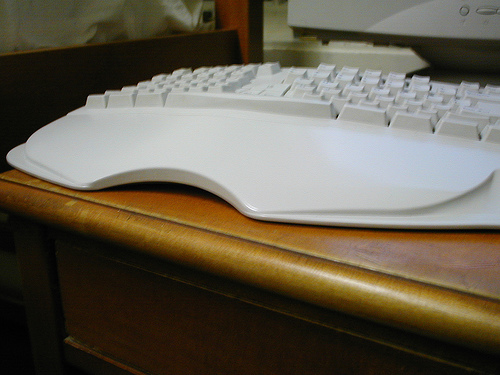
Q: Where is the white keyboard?
A: On the desk.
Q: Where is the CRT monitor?
A: Behind the keyboard.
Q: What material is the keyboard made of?
A: Plastic.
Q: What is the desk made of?
A: Wood.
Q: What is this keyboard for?
A: Personal computers.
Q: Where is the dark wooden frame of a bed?
A: Behind the desk.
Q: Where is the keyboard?
A: On the wood desk.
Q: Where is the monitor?
A: Behind the keyboard.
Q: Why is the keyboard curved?
A: The keyboard is ergonomic.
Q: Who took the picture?
A: A keyboard photographer.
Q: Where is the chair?
A: Beside the desk.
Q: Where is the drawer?
A: In front of the desk.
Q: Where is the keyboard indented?
A: At the bottom.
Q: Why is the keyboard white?
A: To match the monitor.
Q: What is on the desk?
A: A keyboard.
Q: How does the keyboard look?
A: White.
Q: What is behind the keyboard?
A: A monitor.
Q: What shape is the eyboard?
A: Curved.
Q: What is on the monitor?
A: A small round button.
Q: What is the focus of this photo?
A: A keyboard.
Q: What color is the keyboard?
A: White.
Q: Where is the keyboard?
A: A desk.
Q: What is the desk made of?
A: Brown wood.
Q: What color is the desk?
A: Brown.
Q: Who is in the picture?
A: There are not any people in the picture.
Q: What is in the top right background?
A: A part of the monitor.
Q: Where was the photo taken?
A: At a computer desk.